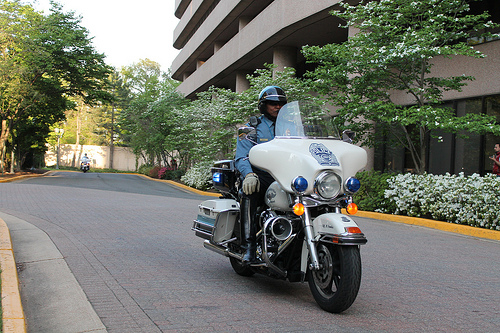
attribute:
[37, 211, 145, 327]
pavement — black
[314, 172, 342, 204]
light — center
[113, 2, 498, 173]
trees — old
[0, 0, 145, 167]
trees — old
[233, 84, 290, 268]
officer — police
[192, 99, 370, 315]
motorcycle — white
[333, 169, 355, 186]
light — blue, side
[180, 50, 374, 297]
police — escort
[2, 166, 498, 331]
street — concrete, bricks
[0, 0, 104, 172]
tree — tall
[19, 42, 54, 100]
leaves — green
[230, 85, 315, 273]
officer — police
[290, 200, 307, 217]
side light — orange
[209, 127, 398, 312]
rider — police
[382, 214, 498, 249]
strip — sidewalk, yellow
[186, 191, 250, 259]
space — cargo